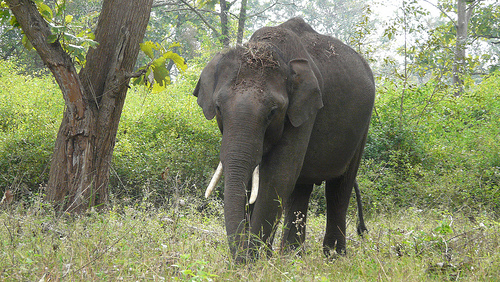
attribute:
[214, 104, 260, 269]
trunk — elephant, ivory, stout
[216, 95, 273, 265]
trunk — elephant, ivory, stout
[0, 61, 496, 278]
grass — wild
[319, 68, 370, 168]
side — gray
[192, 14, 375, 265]
elephant — grey, stout, gray, dark gray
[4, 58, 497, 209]
bushes — Green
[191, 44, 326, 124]
elephant's ears — flat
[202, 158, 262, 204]
elephant's tusk — white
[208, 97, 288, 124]
eyes — elephant's, black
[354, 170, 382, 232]
tail — long, elephant's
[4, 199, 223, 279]
plants — dried out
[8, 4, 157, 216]
trunk — tree, brown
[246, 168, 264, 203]
tusk — ivory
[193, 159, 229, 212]
tusk — stout, ivory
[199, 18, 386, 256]
elephant — large, grey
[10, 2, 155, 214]
tree —   of bark,  brown, large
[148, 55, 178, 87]
leaves —  tree's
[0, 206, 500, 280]
grass —  ground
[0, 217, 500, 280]
grass —   green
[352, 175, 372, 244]
tail — gray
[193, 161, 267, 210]
tusks — white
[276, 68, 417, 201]
ear — grey